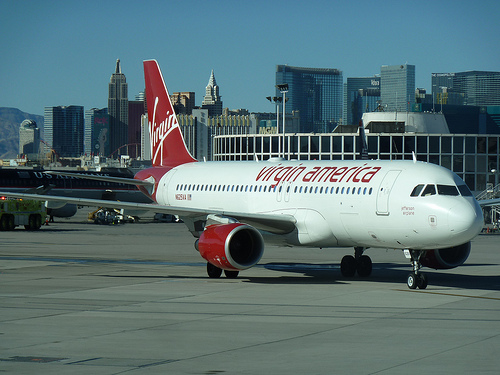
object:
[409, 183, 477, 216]
cockpit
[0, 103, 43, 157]
mountain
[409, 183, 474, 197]
front window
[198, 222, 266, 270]
engine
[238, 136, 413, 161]
windows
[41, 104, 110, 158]
buildings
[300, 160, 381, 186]
word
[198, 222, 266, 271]
red turbine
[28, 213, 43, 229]
tire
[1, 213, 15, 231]
tire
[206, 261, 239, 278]
tire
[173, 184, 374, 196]
windows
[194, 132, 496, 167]
walls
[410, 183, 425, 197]
window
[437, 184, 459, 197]
window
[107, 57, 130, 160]
building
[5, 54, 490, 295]
park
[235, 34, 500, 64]
sky line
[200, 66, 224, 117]
building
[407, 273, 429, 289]
wheel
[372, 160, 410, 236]
door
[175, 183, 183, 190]
window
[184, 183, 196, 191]
window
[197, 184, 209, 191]
window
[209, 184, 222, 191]
window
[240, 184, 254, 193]
window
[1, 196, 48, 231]
truck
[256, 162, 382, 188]
company name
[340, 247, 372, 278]
landing gear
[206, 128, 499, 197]
building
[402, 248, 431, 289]
landing gear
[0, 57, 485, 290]
airplane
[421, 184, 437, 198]
window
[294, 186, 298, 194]
window